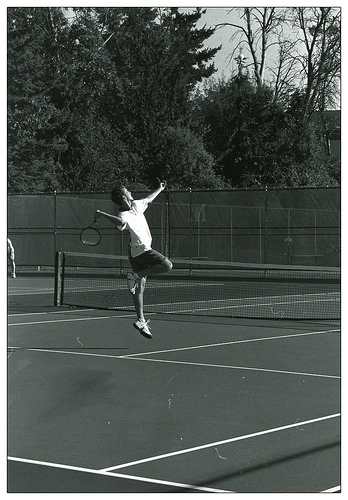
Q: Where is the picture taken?
A: Tennis court.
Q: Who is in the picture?
A: A man.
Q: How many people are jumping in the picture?
A: One.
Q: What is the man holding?
A: A racket.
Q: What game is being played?
A: Tennis.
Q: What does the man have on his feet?
A: Tennis shoes.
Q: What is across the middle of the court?
A: Net.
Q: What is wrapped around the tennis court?
A: Fence.